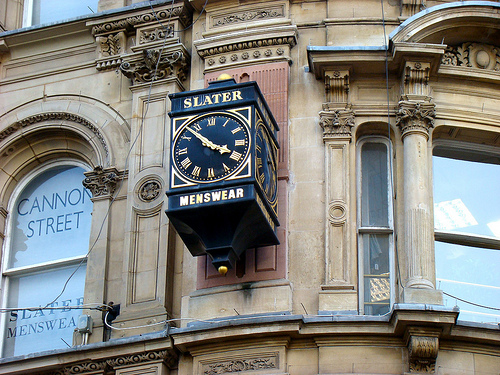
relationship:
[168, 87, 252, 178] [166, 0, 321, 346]
blue clock in wall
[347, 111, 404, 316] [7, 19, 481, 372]
window of building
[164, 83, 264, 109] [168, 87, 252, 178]
brandname written in blue clock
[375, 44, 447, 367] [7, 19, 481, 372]
design in building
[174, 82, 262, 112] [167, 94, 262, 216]
slater written on clock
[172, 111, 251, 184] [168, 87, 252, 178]
clock face of blue clock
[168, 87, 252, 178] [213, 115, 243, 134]
blue clock written in roman numerals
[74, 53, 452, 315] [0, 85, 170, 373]
building on street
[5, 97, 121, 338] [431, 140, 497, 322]
arch over window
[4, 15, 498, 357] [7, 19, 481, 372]
exterior of a building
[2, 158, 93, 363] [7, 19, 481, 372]
arched window on building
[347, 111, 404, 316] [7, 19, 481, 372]
window on building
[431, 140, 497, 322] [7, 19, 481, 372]
window on building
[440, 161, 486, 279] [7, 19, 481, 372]
lights in building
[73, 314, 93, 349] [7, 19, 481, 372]
electrical box on building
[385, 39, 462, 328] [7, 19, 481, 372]
column on building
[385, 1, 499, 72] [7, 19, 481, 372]
arch on building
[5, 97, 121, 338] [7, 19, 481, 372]
arch on building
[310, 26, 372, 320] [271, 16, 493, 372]
stone column on a building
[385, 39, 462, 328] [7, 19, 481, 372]
column on a building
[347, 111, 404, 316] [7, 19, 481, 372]
window on a building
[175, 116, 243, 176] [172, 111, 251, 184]
numbers on a clock face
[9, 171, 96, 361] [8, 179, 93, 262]
poster with streetname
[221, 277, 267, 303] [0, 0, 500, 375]
black mark on a building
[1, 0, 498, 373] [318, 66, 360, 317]
pillar on a building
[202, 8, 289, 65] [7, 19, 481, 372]
decorations on a building